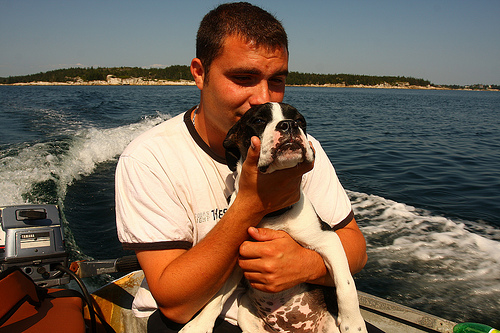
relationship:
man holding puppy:
[112, 3, 366, 329] [177, 104, 376, 332]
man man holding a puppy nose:
[112, 3, 366, 329] [249, 82, 275, 105]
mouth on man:
[232, 106, 265, 125] [112, 3, 366, 329]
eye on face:
[288, 114, 300, 127] [221, 101, 316, 172]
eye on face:
[217, 55, 262, 100] [198, 27, 313, 138]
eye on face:
[262, 71, 292, 94] [198, 27, 313, 138]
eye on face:
[221, 64, 260, 87] [181, 6, 317, 145]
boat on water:
[0, 201, 499, 331] [2, 82, 494, 312]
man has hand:
[112, 3, 366, 329] [237, 222, 318, 293]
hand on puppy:
[237, 222, 318, 293] [177, 104, 376, 332]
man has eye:
[112, 3, 366, 329] [235, 69, 260, 82]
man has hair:
[112, 3, 366, 329] [186, 1, 299, 64]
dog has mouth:
[180, 103, 350, 330] [262, 130, 331, 175]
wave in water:
[0, 106, 177, 265] [2, 82, 494, 312]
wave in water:
[340, 183, 497, 308] [2, 82, 494, 312]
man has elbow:
[112, 3, 366, 329] [147, 261, 215, 324]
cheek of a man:
[211, 77, 253, 116] [168, 12, 354, 219]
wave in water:
[340, 157, 495, 307] [5, 86, 499, 331]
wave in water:
[340, 157, 495, 307] [297, 85, 490, 205]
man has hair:
[112, 3, 366, 329] [193, 2, 290, 84]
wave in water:
[0, 106, 177, 265] [8, 80, 112, 181]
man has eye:
[112, 3, 366, 329] [270, 75, 285, 84]